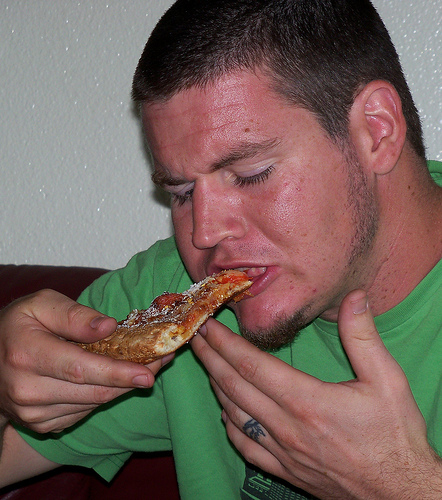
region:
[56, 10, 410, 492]
Man eatting a pissa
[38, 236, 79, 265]
Part of shiny white wall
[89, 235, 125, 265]
Part of shiny white wall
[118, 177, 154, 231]
Part of shiny white wall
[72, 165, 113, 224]
Part of shiny white wall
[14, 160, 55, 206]
Part of shiny white wall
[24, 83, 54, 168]
Part of shiny white wall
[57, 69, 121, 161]
Part of shiny white wall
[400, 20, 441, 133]
Part of shiny white wall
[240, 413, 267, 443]
tattoo on man's finger.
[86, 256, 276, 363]
man is eating pizza.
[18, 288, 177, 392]
pizza in man's hand.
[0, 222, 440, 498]
man's shirt is green.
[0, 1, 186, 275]
the wall is white.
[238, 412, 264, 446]
the tattoo is black.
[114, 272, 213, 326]
the parmesan is white.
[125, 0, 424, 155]
the man's hair is brown.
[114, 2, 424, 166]
the man's hair is short.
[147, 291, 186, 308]
pepperoni on the pizza.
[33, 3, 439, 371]
The man is eating a slice of pizza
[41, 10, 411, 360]
The man is eating a pizza slice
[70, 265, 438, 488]
The man is wearing a green shirt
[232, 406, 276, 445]
The man has a tattoo on his finger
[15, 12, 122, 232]
The wall is a white color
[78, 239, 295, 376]
The man is biting into the pizza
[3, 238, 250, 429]
The man is holding a pizza slice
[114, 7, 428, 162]
The man has short brown hair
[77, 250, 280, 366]
The man bites into the pizza slice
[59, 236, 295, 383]
The man is consuming the pizza slice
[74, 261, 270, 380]
a piece of cheesy pizza.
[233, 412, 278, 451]
a tattoo on a finger.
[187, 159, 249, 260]
a nose on a man's face.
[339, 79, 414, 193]
a left human ear.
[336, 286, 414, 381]
a human left hand thumb.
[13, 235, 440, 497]
A green t shirt.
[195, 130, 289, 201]
a man with long eye lashes.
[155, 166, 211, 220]
an eye with feminine eye lashes.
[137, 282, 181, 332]
pepperoni on a pizza.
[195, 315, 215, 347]
a fingernail on a finger.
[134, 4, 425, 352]
a man with short brown hair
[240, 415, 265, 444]
man with a tattoo on his ring finger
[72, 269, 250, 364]
a slice of pizza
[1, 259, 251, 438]
man holding a slice of pizza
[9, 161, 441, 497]
man wearing a green T-shirt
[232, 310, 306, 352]
man with a goatee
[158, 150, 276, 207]
man with his eyes closed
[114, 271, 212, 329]
Parmesan cheese on a pizza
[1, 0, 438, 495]
a man eating a slice of pizza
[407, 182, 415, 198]
two mall freckles on man's neck